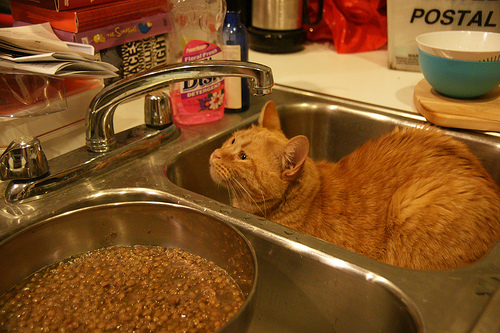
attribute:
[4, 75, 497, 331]
sink — metallic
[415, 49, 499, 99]
blue bowl — plastic 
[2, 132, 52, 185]
opener — silver 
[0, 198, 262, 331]
bowl — large, stainless steel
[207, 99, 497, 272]
fur — brown 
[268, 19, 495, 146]
chopping board — wooden 